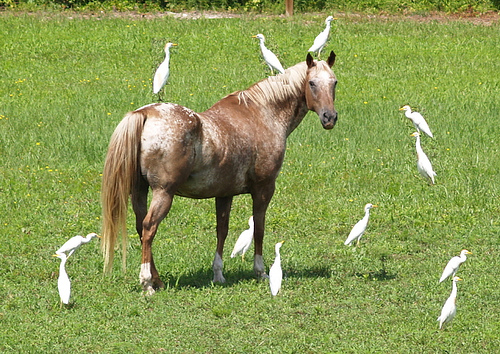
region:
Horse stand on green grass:
[78, 46, 349, 291]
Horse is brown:
[92, 44, 346, 296]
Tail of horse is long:
[91, 106, 149, 289]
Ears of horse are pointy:
[298, 43, 340, 73]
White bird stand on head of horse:
[307, 12, 341, 71]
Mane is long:
[239, 59, 313, 110]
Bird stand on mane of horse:
[243, 22, 295, 79]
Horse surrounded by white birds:
[48, 5, 483, 352]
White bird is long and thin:
[146, 36, 187, 108]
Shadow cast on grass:
[288, 253, 405, 293]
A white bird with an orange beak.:
[152, 41, 177, 101]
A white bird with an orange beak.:
[250, 32, 285, 75]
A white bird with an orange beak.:
[307, 16, 339, 59]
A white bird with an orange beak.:
[54, 231, 102, 259]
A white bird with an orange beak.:
[52, 251, 70, 307]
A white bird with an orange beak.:
[268, 239, 287, 295]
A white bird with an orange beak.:
[343, 202, 379, 247]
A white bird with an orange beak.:
[409, 131, 439, 183]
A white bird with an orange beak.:
[396, 104, 437, 141]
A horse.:
[98, 50, 338, 293]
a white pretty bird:
[46, 247, 80, 307]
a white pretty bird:
[56, 227, 103, 257]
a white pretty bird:
[261, 233, 290, 295]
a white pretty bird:
[226, 207, 256, 264]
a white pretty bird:
[341, 195, 388, 260]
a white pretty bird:
[438, 271, 470, 341]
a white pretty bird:
[436, 242, 479, 292]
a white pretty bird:
[408, 129, 441, 185]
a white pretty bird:
[393, 104, 441, 146]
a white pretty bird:
[251, 28, 288, 72]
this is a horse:
[132, 65, 340, 320]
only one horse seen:
[117, 60, 334, 276]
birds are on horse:
[135, 25, 342, 130]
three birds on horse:
[135, 16, 357, 82]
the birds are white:
[343, 197, 468, 317]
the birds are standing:
[227, 220, 482, 312]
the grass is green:
[293, 223, 455, 347]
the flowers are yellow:
[7, 60, 41, 107]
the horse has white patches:
[135, 100, 280, 246]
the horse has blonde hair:
[107, 99, 145, 254]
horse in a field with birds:
[39, 13, 484, 335]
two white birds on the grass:
[418, 241, 488, 331]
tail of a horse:
[89, 111, 155, 285]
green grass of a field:
[354, 23, 491, 98]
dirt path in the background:
[370, 7, 495, 32]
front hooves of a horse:
[199, 263, 269, 286]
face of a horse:
[303, 45, 346, 137]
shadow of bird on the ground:
[358, 241, 403, 297]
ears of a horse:
[299, 50, 341, 69]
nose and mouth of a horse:
[311, 108, 353, 133]